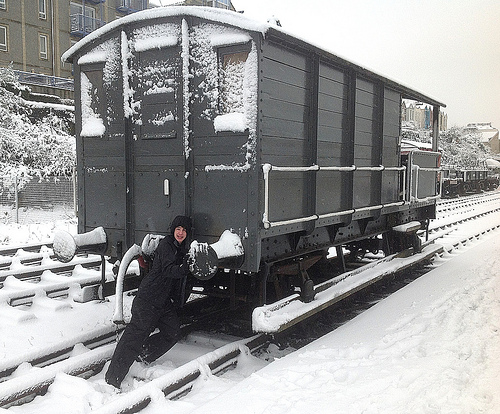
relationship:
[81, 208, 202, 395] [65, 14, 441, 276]
person on train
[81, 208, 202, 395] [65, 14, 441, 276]
person pushing train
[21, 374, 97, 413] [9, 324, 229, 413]
snow covering tracks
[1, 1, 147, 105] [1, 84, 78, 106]
building in background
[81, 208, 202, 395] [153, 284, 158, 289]
person wearing black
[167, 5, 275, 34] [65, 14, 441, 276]
snow on train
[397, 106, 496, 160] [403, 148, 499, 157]
structures in background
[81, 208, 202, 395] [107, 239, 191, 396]
person in snow suit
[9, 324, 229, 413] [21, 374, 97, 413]
tracks with snow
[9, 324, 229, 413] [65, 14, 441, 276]
tracks of train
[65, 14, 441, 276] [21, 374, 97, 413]
train in snow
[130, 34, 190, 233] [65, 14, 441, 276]
door to train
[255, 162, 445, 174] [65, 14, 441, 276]
rails on train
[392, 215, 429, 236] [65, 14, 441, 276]
steps to train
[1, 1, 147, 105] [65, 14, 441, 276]
building next train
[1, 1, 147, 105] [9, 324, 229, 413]
building next tracks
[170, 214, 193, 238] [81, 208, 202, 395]
hood covering person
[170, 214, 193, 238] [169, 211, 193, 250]
hood covering head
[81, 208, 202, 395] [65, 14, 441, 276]
boy pushing train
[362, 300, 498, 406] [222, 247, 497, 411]
footprints in snow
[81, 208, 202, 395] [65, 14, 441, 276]
boy against train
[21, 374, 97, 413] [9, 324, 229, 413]
snow on tracks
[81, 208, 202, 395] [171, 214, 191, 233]
boy with hood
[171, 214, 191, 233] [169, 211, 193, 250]
hood on head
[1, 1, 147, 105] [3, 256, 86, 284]
building next track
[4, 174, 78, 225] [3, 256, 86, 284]
fence near track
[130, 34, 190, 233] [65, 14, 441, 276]
door of railroad car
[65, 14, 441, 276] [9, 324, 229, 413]
train on tracks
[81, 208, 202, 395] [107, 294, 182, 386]
person wearing pants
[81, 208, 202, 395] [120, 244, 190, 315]
person wearing coat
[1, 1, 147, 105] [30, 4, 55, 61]
building with windows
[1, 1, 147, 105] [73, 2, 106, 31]
building with balconies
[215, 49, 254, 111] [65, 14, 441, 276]
window on train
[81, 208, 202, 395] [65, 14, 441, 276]
man against train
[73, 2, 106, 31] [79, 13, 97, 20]
balconies with snow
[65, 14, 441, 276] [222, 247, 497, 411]
train in snow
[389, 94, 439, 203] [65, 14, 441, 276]
deck on train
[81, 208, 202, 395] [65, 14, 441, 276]
kid push train